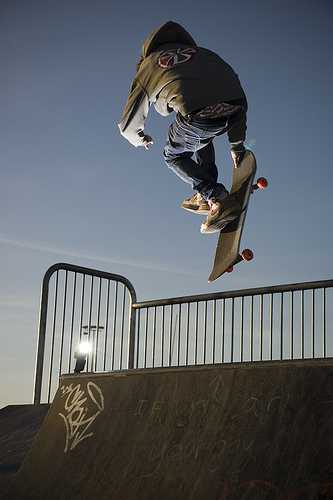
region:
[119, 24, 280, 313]
Man on a skateboard.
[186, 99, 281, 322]
Skateboard under the skater.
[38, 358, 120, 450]
Graffiti on the skate ramp.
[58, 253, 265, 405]
Fence above the ramp.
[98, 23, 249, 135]
Skater wearing a hoodie.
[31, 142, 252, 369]
Sky in the background.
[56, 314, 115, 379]
Light on the skate ramp.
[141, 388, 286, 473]
Words on the skate ramp.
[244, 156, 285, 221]
Orange wheels on the board.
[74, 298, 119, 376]
Light in the background.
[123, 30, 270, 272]
Person riding skateboard in the air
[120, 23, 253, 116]
Person wearing khaki colored hooded sweatshirt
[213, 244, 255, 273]
Skateboard's orange wheels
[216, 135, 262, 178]
Person's hand holding skateboard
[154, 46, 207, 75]
Red and white graphic on person's sweatshirt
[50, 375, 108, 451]
White graffiti on cement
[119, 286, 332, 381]
Metal fence atop Skateboard ramp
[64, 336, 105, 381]
Lighted spotlight at top of skateboard ramp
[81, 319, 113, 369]
Lamp post behind skateboard ramp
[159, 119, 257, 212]
Skateboarder wearing blue jeans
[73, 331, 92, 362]
light on in a spotlight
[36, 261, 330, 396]
gray metal fence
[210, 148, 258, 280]
black skateboard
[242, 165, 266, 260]
small red right wheels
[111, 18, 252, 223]
skateboarder in the air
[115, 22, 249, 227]
skateboarder wearing gray jacket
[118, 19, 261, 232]
skateboarder wearing blue jeans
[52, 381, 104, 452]
white graffiti in the floor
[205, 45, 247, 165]
right hand holding black skateboard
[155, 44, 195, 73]
red and white symbol in the back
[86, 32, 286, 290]
Boy and skateboard in the air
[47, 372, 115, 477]
White graffiti on wall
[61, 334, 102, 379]
A light shinning upward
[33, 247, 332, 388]
a silver metal railing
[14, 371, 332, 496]
a brown cement wall with writing on it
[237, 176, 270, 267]
Red wheels of a skateboard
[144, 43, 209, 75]
Black cross on back of shirt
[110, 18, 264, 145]
a green hoodie worn by boy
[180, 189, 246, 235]
Nike shoes on his feet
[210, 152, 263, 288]
A black skateboard with red wheels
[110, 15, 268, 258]
man jumping next to skateboard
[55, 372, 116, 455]
white graffiti on ramp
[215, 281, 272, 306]
metal pole on fence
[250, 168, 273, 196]
red wheel on skateboard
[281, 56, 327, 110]
blue of daytime sky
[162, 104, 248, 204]
blue jeans on skaters body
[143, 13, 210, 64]
hood on back of sweatshirt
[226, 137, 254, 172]
hand on edge of skateboar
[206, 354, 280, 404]
top edge of ramp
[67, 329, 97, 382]
glowing white light in corner